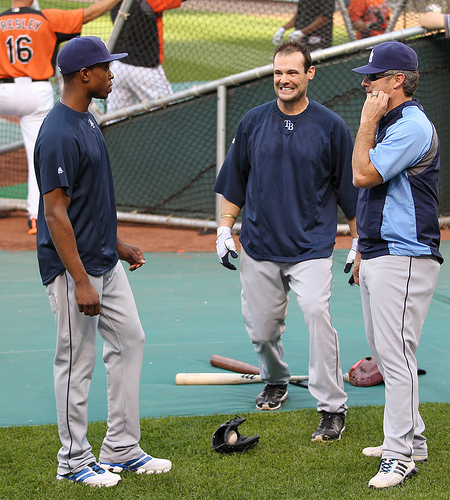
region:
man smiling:
[252, 44, 334, 122]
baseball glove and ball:
[202, 394, 271, 481]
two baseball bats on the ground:
[160, 351, 314, 402]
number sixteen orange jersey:
[0, 4, 54, 80]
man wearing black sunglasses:
[346, 47, 429, 125]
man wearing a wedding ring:
[345, 31, 430, 129]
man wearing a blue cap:
[45, 34, 126, 157]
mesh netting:
[168, 4, 268, 122]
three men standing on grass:
[39, 38, 446, 318]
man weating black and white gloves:
[207, 182, 367, 289]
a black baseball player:
[33, 35, 171, 488]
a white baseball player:
[213, 42, 359, 439]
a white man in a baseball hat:
[351, 41, 443, 489]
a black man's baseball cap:
[59, 37, 128, 73]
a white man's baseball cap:
[349, 38, 419, 72]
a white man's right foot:
[369, 455, 417, 487]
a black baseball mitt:
[213, 415, 258, 454]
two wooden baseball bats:
[173, 353, 313, 386]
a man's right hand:
[212, 226, 241, 269]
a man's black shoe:
[316, 409, 345, 442]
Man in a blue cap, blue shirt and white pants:
[26, 21, 157, 492]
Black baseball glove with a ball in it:
[202, 407, 267, 462]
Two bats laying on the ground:
[164, 341, 302, 411]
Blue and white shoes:
[56, 430, 174, 498]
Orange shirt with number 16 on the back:
[1, 1, 55, 82]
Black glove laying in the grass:
[186, 410, 294, 485]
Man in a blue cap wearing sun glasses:
[352, 28, 434, 110]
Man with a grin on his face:
[249, 29, 336, 114]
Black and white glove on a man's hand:
[209, 220, 250, 272]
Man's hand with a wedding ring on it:
[359, 86, 402, 127]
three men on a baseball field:
[22, 29, 449, 493]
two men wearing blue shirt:
[26, 18, 349, 476]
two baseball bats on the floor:
[173, 345, 357, 397]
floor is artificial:
[12, 242, 449, 403]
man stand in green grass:
[20, 16, 180, 489]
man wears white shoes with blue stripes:
[22, 19, 182, 492]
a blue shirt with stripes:
[345, 96, 441, 276]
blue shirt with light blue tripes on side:
[346, 97, 445, 271]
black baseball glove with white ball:
[200, 403, 268, 458]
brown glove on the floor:
[341, 348, 428, 390]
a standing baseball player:
[29, 30, 179, 498]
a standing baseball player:
[205, 35, 361, 434]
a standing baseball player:
[340, 36, 438, 498]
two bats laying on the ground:
[172, 349, 316, 394]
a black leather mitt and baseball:
[211, 416, 258, 456]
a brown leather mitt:
[345, 353, 382, 389]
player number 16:
[3, 31, 36, 69]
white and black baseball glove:
[214, 224, 237, 273]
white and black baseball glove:
[342, 235, 358, 285]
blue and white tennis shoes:
[50, 450, 172, 487]